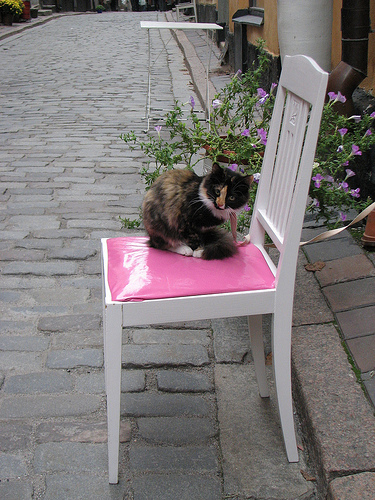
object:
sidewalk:
[0, 10, 322, 498]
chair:
[100, 53, 330, 485]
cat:
[139, 161, 254, 256]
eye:
[229, 195, 236, 202]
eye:
[213, 187, 220, 195]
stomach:
[183, 222, 222, 242]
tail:
[202, 227, 238, 260]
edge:
[1, 9, 91, 39]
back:
[248, 54, 329, 280]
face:
[205, 174, 249, 211]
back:
[143, 166, 198, 239]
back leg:
[248, 315, 270, 399]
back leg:
[271, 314, 299, 463]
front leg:
[104, 304, 123, 485]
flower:
[330, 91, 347, 107]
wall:
[195, 0, 374, 234]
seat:
[106, 235, 274, 303]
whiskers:
[188, 195, 214, 205]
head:
[206, 160, 255, 211]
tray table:
[138, 17, 224, 132]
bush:
[126, 35, 374, 232]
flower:
[250, 86, 267, 101]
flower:
[345, 142, 362, 158]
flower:
[343, 169, 355, 181]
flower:
[338, 127, 349, 139]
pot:
[1, 12, 18, 21]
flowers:
[10, 0, 18, 10]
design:
[288, 100, 300, 128]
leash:
[230, 200, 374, 252]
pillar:
[276, 1, 333, 71]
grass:
[332, 319, 374, 404]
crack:
[334, 322, 374, 414]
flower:
[312, 173, 325, 189]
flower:
[251, 128, 269, 146]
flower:
[349, 187, 360, 202]